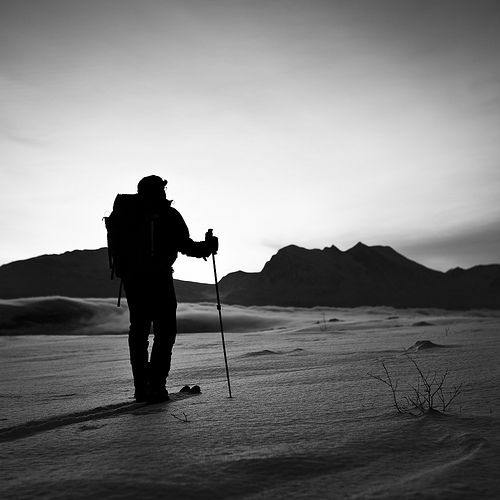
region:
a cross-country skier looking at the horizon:
[101, 174, 234, 401]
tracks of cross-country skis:
[0, 394, 137, 451]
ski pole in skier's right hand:
[205, 226, 237, 398]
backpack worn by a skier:
[103, 192, 155, 294]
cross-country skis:
[117, 382, 202, 417]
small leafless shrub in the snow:
[363, 344, 469, 421]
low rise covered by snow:
[0, 292, 122, 334]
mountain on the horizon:
[221, 240, 446, 309]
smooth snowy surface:
[165, 390, 380, 497]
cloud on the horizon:
[387, 185, 497, 262]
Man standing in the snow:
[91, 135, 259, 438]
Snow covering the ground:
[50, 451, 140, 498]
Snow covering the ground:
[150, 444, 245, 496]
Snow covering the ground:
[250, 441, 323, 493]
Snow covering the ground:
[325, 436, 385, 496]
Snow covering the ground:
[385, 426, 457, 478]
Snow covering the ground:
[322, 351, 403, 419]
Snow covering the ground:
[269, 367, 329, 419]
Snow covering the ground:
[207, 377, 288, 439]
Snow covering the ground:
[49, 326, 89, 372]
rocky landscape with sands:
[4, 215, 498, 497]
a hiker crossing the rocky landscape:
[84, 169, 259, 418]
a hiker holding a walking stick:
[102, 171, 239, 408]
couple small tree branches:
[362, 338, 466, 417]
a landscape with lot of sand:
[253, 310, 498, 380]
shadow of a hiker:
[0, 387, 122, 454]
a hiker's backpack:
[98, 192, 168, 290]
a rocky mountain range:
[225, 227, 497, 314]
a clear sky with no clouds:
[12, 11, 497, 168]